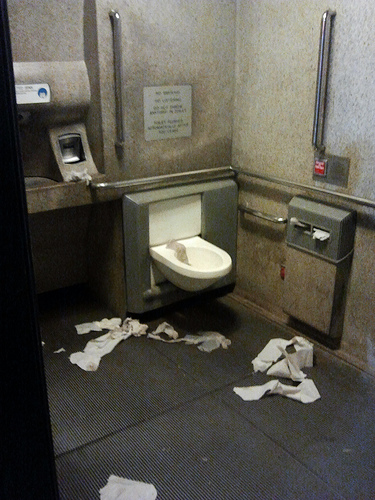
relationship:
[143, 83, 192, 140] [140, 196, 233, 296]
sign above toilet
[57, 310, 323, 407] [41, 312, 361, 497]
toilet paper on floor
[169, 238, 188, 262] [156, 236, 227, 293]
tissue in commode bowl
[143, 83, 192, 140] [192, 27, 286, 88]
sign on wall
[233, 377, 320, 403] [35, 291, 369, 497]
trash on floor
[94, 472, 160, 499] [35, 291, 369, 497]
paper on floor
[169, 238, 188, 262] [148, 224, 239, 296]
tissue on toilet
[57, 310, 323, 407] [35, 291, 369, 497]
toilet paper on floor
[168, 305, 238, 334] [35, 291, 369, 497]
shadow on floor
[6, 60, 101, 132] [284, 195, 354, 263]
tissue coming out of box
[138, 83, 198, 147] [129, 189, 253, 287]
sign above toilet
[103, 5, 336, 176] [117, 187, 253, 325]
bars around toilet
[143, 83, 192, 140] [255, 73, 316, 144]
sign on wall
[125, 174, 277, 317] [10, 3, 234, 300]
toilet attached to wall